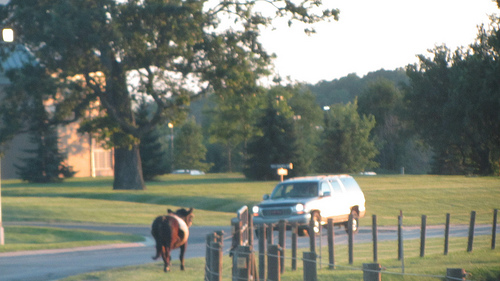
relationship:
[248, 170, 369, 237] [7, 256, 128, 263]
suv on road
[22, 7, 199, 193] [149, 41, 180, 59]
tall tree with leaves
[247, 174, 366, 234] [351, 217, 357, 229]
car with rim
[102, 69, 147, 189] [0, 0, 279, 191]
trunk on tall tree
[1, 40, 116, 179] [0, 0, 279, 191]
house behind tall tree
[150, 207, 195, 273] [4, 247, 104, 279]
animal walking on road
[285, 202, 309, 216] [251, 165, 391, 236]
headligh on suv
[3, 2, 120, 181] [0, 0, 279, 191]
building behind tall tree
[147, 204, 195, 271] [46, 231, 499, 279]
animal on grass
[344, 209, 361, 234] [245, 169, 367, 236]
back tire on car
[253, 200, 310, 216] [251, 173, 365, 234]
lights on suv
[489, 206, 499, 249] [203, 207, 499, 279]
pole on fence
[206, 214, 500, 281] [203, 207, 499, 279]
pole on fence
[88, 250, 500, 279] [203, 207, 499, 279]
grass on fence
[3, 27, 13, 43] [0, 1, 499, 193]
light behind trees